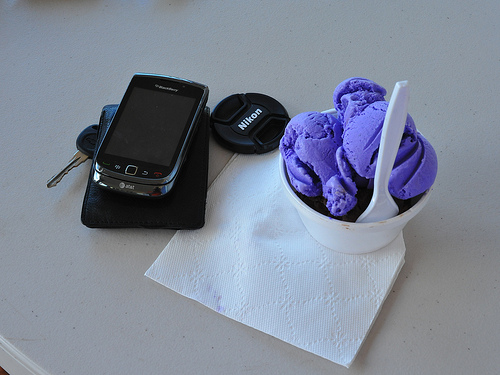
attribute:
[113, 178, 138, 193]
logo — AT&T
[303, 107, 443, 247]
cup — round, white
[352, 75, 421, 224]
spoon — white, plastic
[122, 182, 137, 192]
logo — at&t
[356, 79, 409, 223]
spoon — is white, is plastic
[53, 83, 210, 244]
wallet — is black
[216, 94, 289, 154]
cap — Nikon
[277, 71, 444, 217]
icecream — is purple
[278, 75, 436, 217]
ice cream — is blue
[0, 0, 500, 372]
table — white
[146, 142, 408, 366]
bad napkin — is white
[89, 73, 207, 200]
cellphone — blackberry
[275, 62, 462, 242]
sherbert — blue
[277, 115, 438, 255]
white bowl — is white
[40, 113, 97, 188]
black key — is black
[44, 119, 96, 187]
car key — is black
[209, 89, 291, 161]
camera lens — is black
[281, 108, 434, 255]
cup — is white, is styrofoam